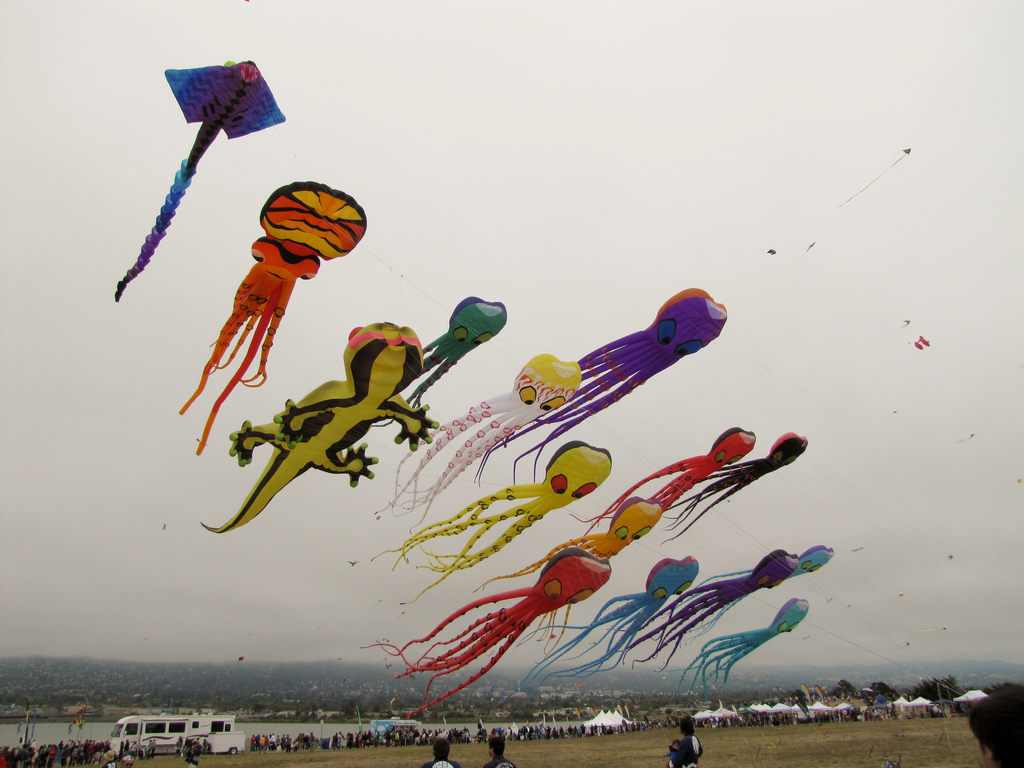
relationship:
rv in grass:
[108, 715, 235, 758] [115, 639, 1021, 766]